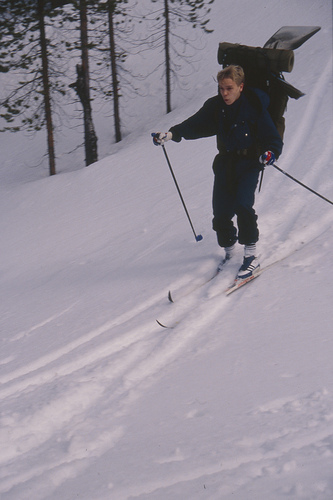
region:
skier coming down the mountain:
[145, 34, 330, 327]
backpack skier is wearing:
[218, 42, 294, 159]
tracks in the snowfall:
[25, 72, 326, 485]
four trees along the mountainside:
[29, 2, 176, 164]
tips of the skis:
[149, 288, 179, 329]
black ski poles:
[155, 134, 329, 255]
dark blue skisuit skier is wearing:
[166, 97, 276, 243]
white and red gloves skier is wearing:
[151, 131, 276, 171]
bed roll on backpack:
[219, 41, 290, 69]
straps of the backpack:
[207, 92, 265, 138]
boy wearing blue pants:
[209, 155, 263, 244]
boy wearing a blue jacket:
[199, 91, 271, 155]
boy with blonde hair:
[210, 65, 246, 94]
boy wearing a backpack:
[217, 33, 292, 158]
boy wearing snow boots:
[215, 245, 259, 282]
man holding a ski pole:
[148, 122, 205, 245]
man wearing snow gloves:
[151, 127, 172, 147]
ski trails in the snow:
[83, 319, 170, 414]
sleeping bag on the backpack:
[213, 37, 293, 69]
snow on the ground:
[108, 390, 320, 486]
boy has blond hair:
[206, 60, 252, 94]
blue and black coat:
[196, 65, 272, 147]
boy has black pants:
[210, 149, 268, 237]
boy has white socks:
[228, 243, 269, 258]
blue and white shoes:
[228, 257, 268, 283]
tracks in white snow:
[89, 286, 230, 389]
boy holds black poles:
[144, 131, 245, 248]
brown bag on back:
[226, 30, 296, 142]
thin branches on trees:
[0, 7, 184, 145]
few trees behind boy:
[39, 8, 193, 170]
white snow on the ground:
[97, 30, 218, 175]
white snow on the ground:
[43, 219, 213, 459]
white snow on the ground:
[243, 255, 315, 419]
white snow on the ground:
[6, 410, 76, 492]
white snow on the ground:
[167, 455, 305, 494]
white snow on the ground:
[15, 185, 96, 324]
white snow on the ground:
[25, 31, 171, 200]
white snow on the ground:
[102, 186, 300, 422]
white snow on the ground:
[125, 3, 319, 327]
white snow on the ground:
[31, 230, 107, 411]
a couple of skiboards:
[155, 261, 263, 326]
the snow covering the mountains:
[12, 173, 134, 259]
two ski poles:
[154, 135, 331, 241]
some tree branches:
[3, 18, 39, 124]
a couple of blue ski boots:
[217, 253, 259, 273]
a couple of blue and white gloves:
[152, 131, 273, 164]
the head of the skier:
[216, 65, 245, 103]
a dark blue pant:
[211, 156, 257, 210]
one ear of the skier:
[239, 83, 243, 90]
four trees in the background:
[8, 1, 181, 123]